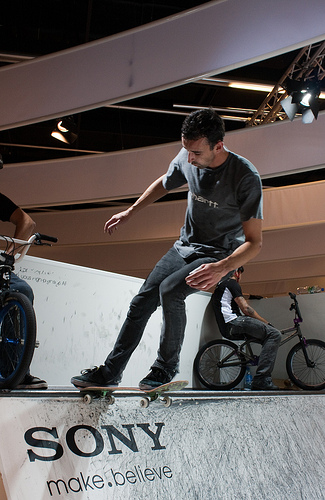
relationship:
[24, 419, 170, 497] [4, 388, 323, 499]
advertisement on ramp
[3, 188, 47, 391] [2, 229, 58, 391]
man resting on bicycle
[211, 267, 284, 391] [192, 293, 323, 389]
man sits on bicycle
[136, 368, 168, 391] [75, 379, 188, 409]
foot on skateboard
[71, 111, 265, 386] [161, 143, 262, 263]
man wearing a shirt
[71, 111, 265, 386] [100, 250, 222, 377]
man wearing jeans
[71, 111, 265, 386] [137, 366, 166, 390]
man wearing a shoe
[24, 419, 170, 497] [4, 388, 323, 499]
advertisement printed on ramp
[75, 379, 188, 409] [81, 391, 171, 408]
skateboard has wheels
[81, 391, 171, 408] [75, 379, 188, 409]
wheels under skateboard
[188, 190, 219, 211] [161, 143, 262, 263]
lettering on shirt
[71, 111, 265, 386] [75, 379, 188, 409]
man riding a skateboard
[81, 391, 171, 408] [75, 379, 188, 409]
wheels are on skateboard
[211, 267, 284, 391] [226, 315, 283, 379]
man wearing jeans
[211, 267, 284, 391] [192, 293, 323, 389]
man sitting on a bicycle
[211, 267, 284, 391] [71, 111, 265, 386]
man behind man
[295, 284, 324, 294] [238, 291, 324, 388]
bottle on wall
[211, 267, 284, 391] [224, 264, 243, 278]
man wearing a helmet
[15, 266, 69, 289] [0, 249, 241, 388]
grafitti on wall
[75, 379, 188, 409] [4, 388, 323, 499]
skateboard on ramp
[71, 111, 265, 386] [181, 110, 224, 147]
man has hair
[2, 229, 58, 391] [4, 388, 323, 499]
bicycle near ramp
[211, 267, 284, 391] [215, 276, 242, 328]
man wearing a shirt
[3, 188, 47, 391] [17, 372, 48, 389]
man wearing a shoe